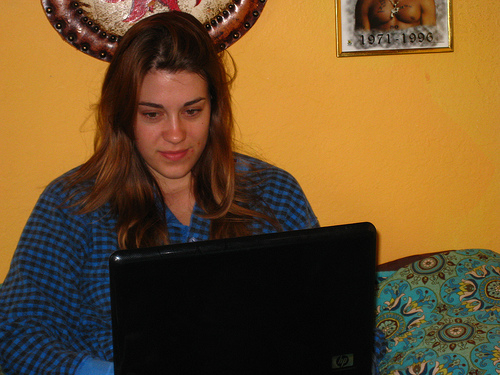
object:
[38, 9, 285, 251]
hair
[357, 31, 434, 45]
dates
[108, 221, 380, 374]
computer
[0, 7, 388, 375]
using laptop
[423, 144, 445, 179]
ground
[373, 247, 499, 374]
cover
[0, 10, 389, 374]
brunette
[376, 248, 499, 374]
upholstery pattern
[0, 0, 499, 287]
wall.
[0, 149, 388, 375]
shirt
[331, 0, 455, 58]
frame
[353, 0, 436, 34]
man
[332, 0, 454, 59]
picture